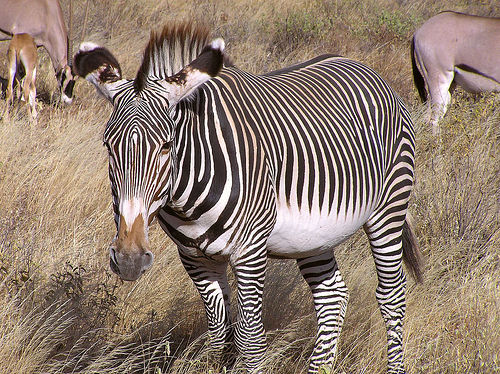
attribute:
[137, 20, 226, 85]
mane — zebra's   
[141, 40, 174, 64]
hairs — straight up 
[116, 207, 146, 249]
spot — brown 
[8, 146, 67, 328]
grass — very high 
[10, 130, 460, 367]
grass — dry, brown 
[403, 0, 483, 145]
animal — upper right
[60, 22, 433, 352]
zebra —  upper left, black , white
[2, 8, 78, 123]
animal — another kind 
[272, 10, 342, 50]
plant — patch , green 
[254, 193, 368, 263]
belly — white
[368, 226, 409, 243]
strip — black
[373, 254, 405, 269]
strip — black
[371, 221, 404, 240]
strip — black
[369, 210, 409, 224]
strip — black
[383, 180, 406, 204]
strip — black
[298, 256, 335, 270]
strip — black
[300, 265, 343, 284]
strip — black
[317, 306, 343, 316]
strip — black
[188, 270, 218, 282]
strip — black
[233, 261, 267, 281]
strip — black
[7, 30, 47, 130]
animal — wild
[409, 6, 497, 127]
animal — wild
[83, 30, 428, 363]
animal — wild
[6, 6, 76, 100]
animal — wild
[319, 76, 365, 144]
stripe — white, black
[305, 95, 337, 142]
stripe — white, black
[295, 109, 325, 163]
stripe — white, black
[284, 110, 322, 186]
stripe — white, black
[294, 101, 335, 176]
stripe — white, black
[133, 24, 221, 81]
mane — black, white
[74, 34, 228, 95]
ears — large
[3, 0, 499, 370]
grass — brown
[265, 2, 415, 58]
plants — green, small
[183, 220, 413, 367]
legs — four 